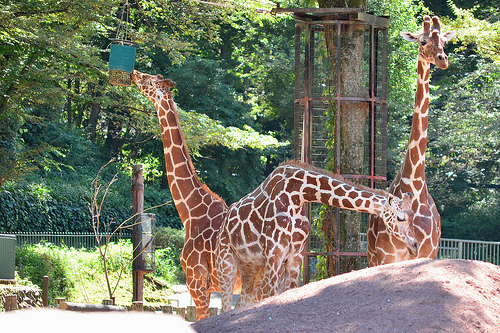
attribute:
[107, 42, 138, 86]
feeder — hanging, green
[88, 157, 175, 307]
tree — bare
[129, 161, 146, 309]
post — brown, tall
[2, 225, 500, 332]
fence — surrounding, grey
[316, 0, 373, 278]
trunk — protected, surrounded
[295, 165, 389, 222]
neck — long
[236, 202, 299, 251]
spots — brown, white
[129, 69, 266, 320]
giraffe — feeding, eating, spotted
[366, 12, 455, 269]
giraffe — standing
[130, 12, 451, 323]
giraffes — three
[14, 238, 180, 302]
bushes — dense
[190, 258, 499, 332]
dirt — mound